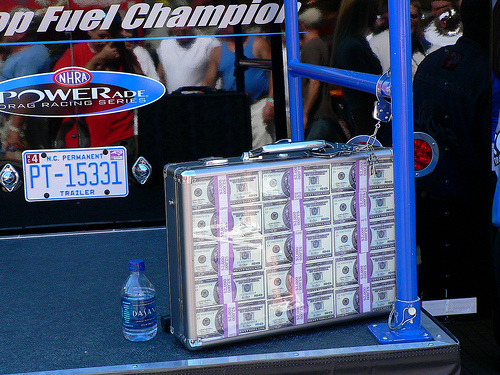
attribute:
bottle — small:
[121, 258, 157, 343]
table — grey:
[1, 223, 461, 373]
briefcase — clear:
[164, 139, 407, 351]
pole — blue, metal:
[369, 0, 431, 347]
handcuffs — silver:
[348, 69, 392, 149]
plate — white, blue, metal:
[21, 146, 129, 202]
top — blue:
[128, 257, 147, 271]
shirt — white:
[155, 35, 222, 95]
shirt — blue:
[218, 36, 268, 102]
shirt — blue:
[0, 43, 52, 119]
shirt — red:
[53, 41, 134, 148]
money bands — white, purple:
[215, 171, 240, 340]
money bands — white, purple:
[289, 165, 310, 329]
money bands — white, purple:
[355, 155, 374, 314]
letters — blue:
[26, 152, 122, 196]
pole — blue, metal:
[284, 0, 307, 146]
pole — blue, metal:
[286, 57, 411, 101]